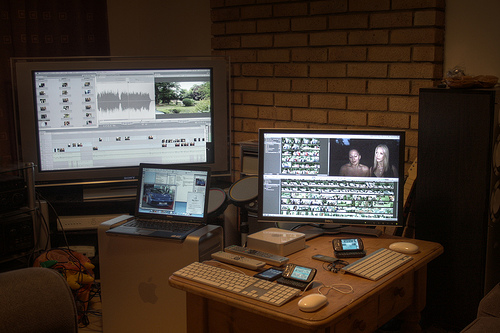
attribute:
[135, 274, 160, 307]
symbol — apple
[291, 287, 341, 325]
mouse — white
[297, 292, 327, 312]
mouse — white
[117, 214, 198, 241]
keyboard — black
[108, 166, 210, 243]
laptop — open, black